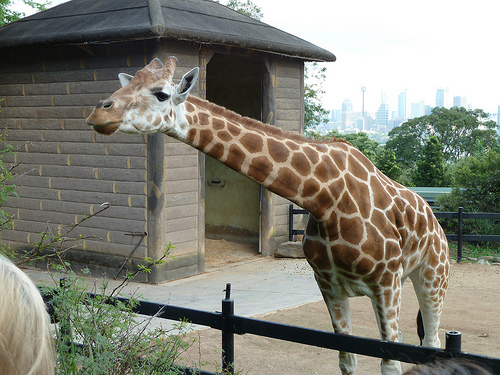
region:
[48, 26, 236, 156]
A giraffe that is looking curious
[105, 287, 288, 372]
A metal fence to keep the giraffe in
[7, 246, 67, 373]
Blonde hair on a person at the zoo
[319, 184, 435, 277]
The giraffe is white and brown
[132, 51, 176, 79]
Horns on the giraffes head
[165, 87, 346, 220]
The long neck of a giraffe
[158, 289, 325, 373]
The metal fence is painted black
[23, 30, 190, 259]
A building for the giraffe to go in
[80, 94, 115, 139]
Lips and nostrils of a giraffe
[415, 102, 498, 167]
The trees in the background are green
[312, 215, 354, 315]
part of a chest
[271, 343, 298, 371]
part of a floor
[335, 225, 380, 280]
part of a chest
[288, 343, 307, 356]
part of a groumd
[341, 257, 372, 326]
part of a chest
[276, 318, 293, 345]
part of a board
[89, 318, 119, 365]
part of a plant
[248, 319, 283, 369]
part of a ground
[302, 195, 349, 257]
part of a chest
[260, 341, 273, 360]
part of a grounmd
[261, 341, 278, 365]
part of a ground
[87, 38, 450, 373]
A spotted giraffe in a zoo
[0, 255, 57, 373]
A hidden animal on the left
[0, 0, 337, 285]
A small stone built structure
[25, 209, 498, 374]
The dark low fenced area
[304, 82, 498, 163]
The city's faint skycrappers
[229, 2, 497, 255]
The green bushes in the background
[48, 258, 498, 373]
An open space in a zoo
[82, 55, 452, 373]
The long necked curious giraffe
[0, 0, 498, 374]
A bright day in a zoo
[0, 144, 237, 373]
The green vegetation on the left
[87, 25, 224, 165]
head of a giraffe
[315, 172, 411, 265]
brown spots on giraffe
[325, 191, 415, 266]
white lines on giraffe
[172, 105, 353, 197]
neck of the giraffe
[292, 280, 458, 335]
legs of the giraffe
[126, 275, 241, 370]
fence in front of giraffe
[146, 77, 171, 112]
eye of the giraffe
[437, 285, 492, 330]
dirt under the giraffe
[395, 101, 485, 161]
trees in the distance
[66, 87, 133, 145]
nose and mouth of giraffe